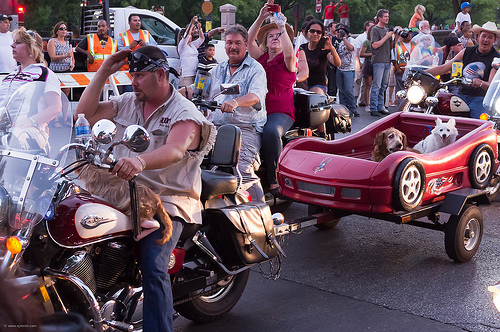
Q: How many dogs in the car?
A: Two.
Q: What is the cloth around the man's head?
A: A bandana.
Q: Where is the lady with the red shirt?
A: On back of the motorcycle.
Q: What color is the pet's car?
A: Red.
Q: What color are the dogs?
A: Brown and white.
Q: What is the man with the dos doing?
A: Riding a motorcycle.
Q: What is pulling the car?
A: A motorcycle.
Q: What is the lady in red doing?
A: Taking a picture.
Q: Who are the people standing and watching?
A: Bystanders.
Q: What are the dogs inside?
A: A trailer.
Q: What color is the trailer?
A: Red.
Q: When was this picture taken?
A: Daytime.